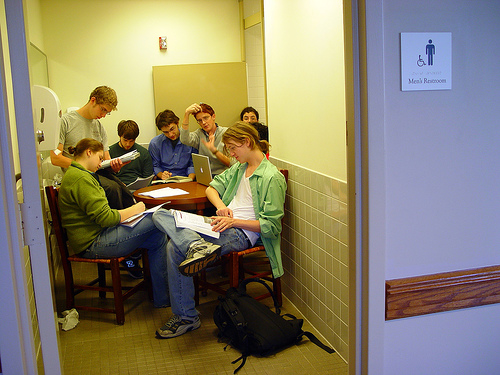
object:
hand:
[210, 215, 236, 235]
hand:
[201, 134, 221, 151]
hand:
[158, 170, 173, 183]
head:
[219, 121, 267, 165]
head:
[154, 108, 184, 143]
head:
[82, 85, 120, 120]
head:
[65, 135, 108, 173]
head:
[114, 120, 142, 149]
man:
[238, 122, 269, 153]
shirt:
[206, 150, 288, 279]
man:
[49, 85, 134, 209]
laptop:
[190, 153, 220, 187]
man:
[180, 102, 235, 177]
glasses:
[196, 115, 212, 125]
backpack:
[205, 275, 339, 375]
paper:
[148, 170, 198, 187]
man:
[148, 110, 196, 187]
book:
[136, 186, 190, 198]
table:
[133, 179, 209, 217]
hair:
[153, 109, 181, 132]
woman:
[57, 137, 167, 307]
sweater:
[58, 162, 113, 252]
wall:
[386, 1, 498, 375]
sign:
[398, 28, 453, 93]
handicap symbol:
[415, 52, 427, 69]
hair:
[220, 120, 274, 155]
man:
[150, 122, 286, 340]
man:
[108, 120, 153, 179]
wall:
[263, 0, 351, 364]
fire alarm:
[158, 37, 168, 51]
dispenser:
[31, 84, 59, 151]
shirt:
[149, 133, 195, 176]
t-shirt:
[55, 110, 107, 155]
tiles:
[325, 252, 331, 273]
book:
[167, 207, 223, 240]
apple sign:
[196, 168, 203, 175]